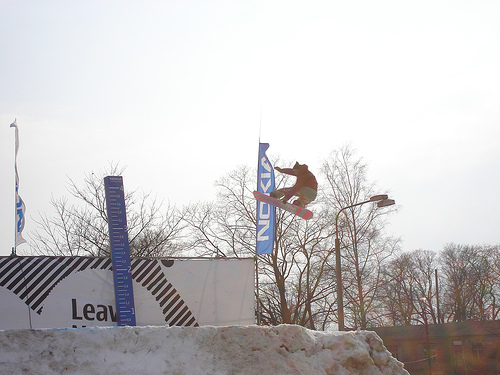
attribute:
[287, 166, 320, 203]
person — jumping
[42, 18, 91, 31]
sky — blue, grey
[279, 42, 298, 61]
clouds — white, thick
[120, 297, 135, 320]
device — blue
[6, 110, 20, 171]
lighting — overhead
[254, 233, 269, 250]
banner — blue, mounted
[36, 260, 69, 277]
tarp — black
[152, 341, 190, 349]
snow — packed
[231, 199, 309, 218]
snowboard — red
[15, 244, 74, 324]
board — black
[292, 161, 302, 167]
cap — black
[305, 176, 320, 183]
jacket — orange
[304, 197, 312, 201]
pants — grey